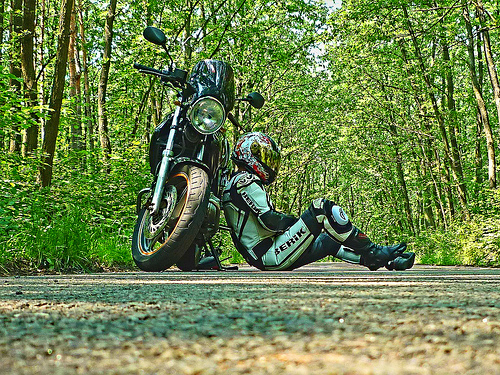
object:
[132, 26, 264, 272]
motor bike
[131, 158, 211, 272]
tire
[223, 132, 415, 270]
motor bike driver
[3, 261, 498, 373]
road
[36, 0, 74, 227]
tree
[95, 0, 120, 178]
tree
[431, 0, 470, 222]
tree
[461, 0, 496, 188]
tree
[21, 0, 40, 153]
tree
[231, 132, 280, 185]
helmet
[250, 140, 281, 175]
lens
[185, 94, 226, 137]
headlight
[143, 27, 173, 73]
rear view mirror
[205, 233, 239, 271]
kick stand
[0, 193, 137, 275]
grass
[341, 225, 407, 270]
boot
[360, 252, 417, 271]
boot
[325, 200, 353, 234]
knee pad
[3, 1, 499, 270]
forest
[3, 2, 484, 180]
sky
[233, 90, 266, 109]
right mirror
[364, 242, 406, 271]
right foot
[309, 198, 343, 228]
right knee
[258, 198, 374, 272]
pants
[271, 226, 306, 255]
logo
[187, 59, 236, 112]
windshield